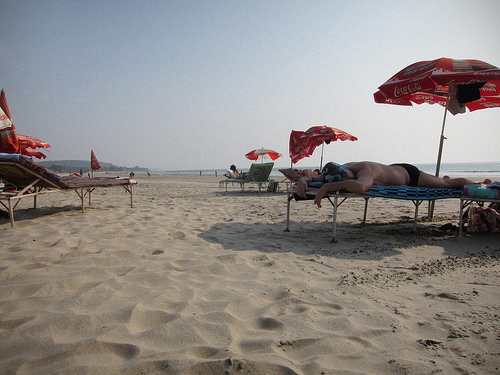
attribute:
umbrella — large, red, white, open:
[383, 49, 494, 176]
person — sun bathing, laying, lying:
[296, 161, 493, 195]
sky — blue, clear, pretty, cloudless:
[1, 1, 496, 159]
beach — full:
[0, 171, 499, 373]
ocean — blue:
[165, 160, 500, 180]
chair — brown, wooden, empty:
[2, 157, 139, 203]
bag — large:
[462, 205, 498, 233]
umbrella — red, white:
[86, 152, 107, 169]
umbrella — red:
[242, 141, 281, 161]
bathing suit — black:
[392, 158, 426, 187]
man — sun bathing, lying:
[301, 160, 492, 207]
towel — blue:
[370, 183, 458, 197]